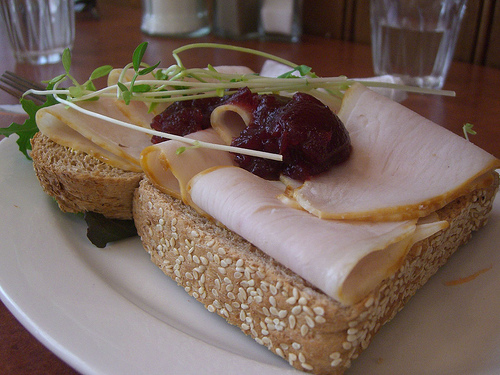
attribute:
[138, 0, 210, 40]
salt — glass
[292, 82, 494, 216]
meat — white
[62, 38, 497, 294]
meat — white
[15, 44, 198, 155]
leaves — green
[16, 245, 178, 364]
plate — white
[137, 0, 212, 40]
container — glass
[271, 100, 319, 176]
sauce — Purple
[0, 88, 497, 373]
plate — white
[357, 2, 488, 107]
glass — clear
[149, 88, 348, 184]
sauce — Purple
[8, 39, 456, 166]
garnish — Green, leafy